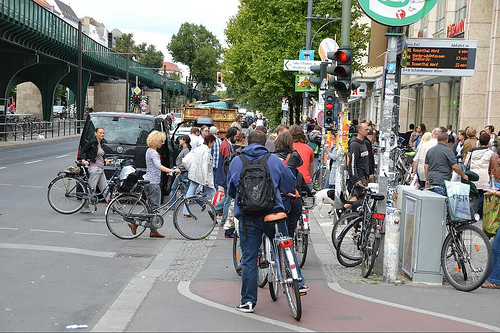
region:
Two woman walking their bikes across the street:
[45, 125, 214, 249]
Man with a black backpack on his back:
[225, 127, 314, 308]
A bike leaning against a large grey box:
[398, 176, 495, 296]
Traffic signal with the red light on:
[325, 33, 357, 110]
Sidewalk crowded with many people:
[317, 102, 499, 267]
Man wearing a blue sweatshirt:
[225, 122, 301, 331]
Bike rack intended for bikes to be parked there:
[5, 103, 52, 141]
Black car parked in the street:
[83, 106, 178, 207]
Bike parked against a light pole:
[329, 170, 399, 290]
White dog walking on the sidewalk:
[308, 179, 346, 221]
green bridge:
[21, 5, 193, 97]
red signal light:
[330, 41, 355, 100]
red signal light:
[309, 74, 336, 131]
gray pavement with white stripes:
[10, 212, 107, 322]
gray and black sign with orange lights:
[400, 32, 481, 96]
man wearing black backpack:
[227, 128, 309, 223]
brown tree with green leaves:
[217, 6, 335, 110]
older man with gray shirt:
[418, 120, 477, 198]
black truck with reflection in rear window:
[78, 86, 178, 216]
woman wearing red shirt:
[286, 112, 321, 190]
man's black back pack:
[233, 143, 280, 222]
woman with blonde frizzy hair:
[141, 125, 171, 237]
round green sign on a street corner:
[353, 2, 443, 32]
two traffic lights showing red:
[317, 47, 354, 123]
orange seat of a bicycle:
[259, 207, 294, 224]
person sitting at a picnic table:
[7, 97, 17, 114]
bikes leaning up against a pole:
[335, 180, 386, 270]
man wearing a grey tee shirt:
[423, 130, 470, 194]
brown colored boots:
[124, 220, 167, 241]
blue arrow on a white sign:
[281, 56, 291, 71]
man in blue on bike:
[223, 133, 312, 328]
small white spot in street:
[43, 301, 130, 330]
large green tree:
[167, 15, 252, 81]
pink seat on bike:
[263, 207, 320, 240]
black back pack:
[225, 142, 297, 234]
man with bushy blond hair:
[135, 126, 185, 158]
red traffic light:
[319, 37, 368, 67]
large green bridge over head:
[28, 10, 198, 82]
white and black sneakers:
[228, 292, 271, 322]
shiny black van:
[65, 111, 173, 203]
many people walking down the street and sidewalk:
[59, 71, 499, 293]